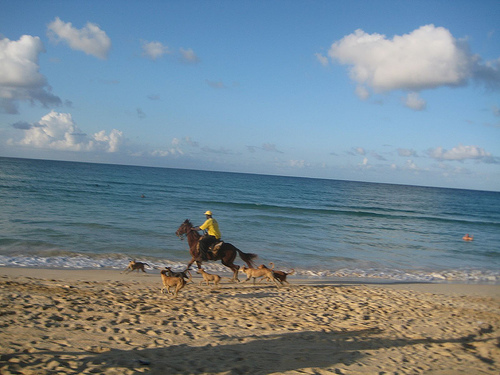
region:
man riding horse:
[171, 199, 258, 276]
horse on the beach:
[167, 216, 259, 276]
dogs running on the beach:
[155, 263, 295, 293]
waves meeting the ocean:
[332, 259, 492, 307]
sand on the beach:
[360, 293, 444, 335]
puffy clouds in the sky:
[332, 29, 483, 109]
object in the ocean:
[452, 225, 479, 250]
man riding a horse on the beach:
[169, 203, 264, 287]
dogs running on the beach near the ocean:
[123, 245, 305, 298]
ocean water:
[20, 153, 141, 230]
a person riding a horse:
[174, 205, 245, 275]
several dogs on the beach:
[114, 254, 306, 306]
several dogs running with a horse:
[114, 240, 304, 313]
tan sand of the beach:
[225, 280, 383, 325]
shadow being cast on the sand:
[61, 315, 393, 373]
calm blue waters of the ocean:
[251, 170, 404, 237]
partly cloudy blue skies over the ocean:
[188, 43, 456, 167]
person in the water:
[447, 224, 486, 250]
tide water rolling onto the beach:
[312, 258, 479, 294]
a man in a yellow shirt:
[195, 202, 229, 249]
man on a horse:
[207, 205, 221, 268]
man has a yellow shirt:
[205, 208, 212, 248]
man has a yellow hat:
[195, 208, 233, 231]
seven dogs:
[107, 238, 306, 308]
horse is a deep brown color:
[190, 228, 246, 277]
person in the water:
[456, 223, 469, 239]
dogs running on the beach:
[126, 250, 295, 303]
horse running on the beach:
[193, 244, 230, 289]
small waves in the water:
[265, 196, 285, 208]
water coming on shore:
[36, 247, 60, 273]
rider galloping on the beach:
[176, 209, 258, 281]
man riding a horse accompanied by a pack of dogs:
[121, 210, 301, 299]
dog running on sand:
[156, 269, 187, 296]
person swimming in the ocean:
[460, 231, 473, 243]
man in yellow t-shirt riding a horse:
[174, 209, 257, 281]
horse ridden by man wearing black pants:
[175, 218, 256, 281]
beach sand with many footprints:
[1, 264, 499, 372]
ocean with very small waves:
[0, 154, 499, 284]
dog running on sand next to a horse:
[176, 218, 256, 287]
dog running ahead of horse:
[116, 217, 256, 283]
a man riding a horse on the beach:
[153, 195, 263, 283]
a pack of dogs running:
[103, 253, 316, 308]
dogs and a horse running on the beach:
[99, 198, 305, 305]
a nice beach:
[1, 0, 496, 373]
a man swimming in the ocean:
[455, 223, 489, 259]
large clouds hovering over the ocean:
[4, 8, 466, 111]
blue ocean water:
[1, 162, 496, 209]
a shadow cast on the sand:
[14, 330, 491, 374]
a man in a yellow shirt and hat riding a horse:
[176, 205, 235, 265]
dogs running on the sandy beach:
[114, 253, 291, 318]